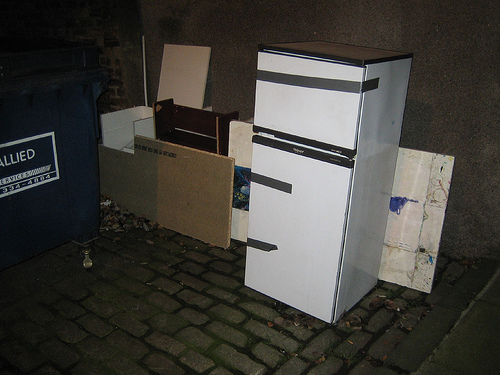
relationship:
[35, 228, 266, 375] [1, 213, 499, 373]
section of floor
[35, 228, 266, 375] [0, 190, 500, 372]
section of floor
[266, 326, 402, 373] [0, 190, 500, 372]
section of floor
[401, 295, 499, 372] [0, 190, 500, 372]
section of floor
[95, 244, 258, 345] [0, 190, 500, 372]
section of floor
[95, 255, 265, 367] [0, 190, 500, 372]
section of floor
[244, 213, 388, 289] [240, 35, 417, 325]
part of fridge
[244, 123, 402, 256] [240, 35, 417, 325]
part of fridge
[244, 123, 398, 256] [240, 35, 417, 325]
part of fridge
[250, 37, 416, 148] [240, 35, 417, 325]
part of fridge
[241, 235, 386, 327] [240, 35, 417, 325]
part of fridge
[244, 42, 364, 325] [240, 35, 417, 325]
door on fridge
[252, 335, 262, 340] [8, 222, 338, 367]
grout between bricks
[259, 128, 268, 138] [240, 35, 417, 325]
duct tape on fridge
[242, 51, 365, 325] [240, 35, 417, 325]
door on fridge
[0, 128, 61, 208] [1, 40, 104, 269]
logo on trash container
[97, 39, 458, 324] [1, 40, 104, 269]
debris beside trash container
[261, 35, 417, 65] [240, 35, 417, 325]
top of fridge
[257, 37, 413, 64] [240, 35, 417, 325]
trim of fridge